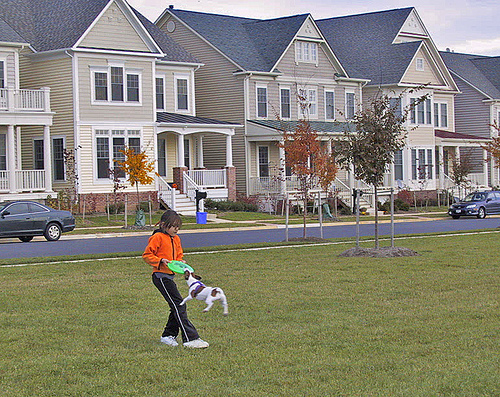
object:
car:
[0, 199, 74, 247]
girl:
[144, 210, 210, 351]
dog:
[178, 269, 230, 318]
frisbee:
[165, 258, 194, 279]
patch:
[190, 286, 206, 298]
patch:
[210, 287, 218, 298]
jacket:
[143, 231, 186, 275]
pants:
[152, 273, 200, 342]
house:
[2, 2, 239, 220]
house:
[152, 4, 373, 216]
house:
[304, 7, 492, 217]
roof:
[1, 1, 204, 68]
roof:
[160, 4, 348, 72]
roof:
[314, 6, 461, 93]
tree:
[124, 142, 155, 230]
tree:
[282, 115, 325, 245]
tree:
[311, 141, 339, 219]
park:
[0, 228, 500, 393]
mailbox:
[194, 189, 208, 212]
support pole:
[355, 188, 360, 252]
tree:
[329, 83, 432, 255]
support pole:
[389, 193, 396, 248]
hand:
[179, 258, 187, 263]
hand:
[162, 257, 173, 265]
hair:
[158, 209, 183, 231]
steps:
[161, 188, 197, 214]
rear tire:
[44, 224, 61, 241]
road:
[1, 217, 499, 260]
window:
[91, 68, 112, 104]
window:
[110, 63, 127, 103]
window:
[94, 135, 114, 181]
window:
[112, 134, 128, 181]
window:
[128, 132, 143, 185]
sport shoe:
[182, 338, 208, 349]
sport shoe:
[159, 334, 179, 347]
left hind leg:
[202, 298, 217, 314]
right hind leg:
[221, 296, 230, 314]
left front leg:
[178, 292, 192, 306]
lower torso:
[150, 258, 177, 271]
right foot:
[183, 337, 210, 349]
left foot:
[161, 333, 180, 348]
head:
[156, 209, 183, 236]